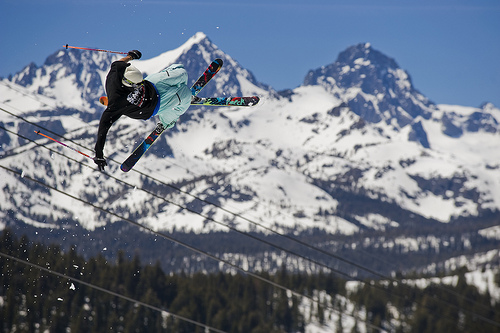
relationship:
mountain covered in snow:
[0, 31, 500, 262] [2, 91, 443, 232]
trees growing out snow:
[0, 217, 499, 328] [133, 131, 347, 236]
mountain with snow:
[6, 44, 99, 144] [0, 77, 73, 115]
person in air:
[89, 47, 198, 169] [0, 0, 500, 327]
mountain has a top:
[0, 31, 500, 262] [55, 27, 399, 67]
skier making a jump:
[89, 47, 198, 169] [14, 15, 287, 232]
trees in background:
[0, 217, 499, 328] [5, 190, 495, 259]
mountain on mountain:
[0, 31, 500, 262] [0, 31, 500, 262]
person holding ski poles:
[89, 47, 198, 169] [31, 37, 124, 161]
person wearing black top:
[89, 47, 198, 169] [90, 58, 140, 155]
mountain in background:
[0, 31, 500, 262] [0, 0, 500, 327]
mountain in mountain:
[0, 31, 500, 262] [0, 31, 500, 262]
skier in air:
[89, 47, 198, 169] [0, 0, 500, 327]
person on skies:
[89, 47, 198, 169] [116, 58, 266, 173]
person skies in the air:
[89, 47, 198, 169] [0, 0, 500, 327]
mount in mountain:
[298, 35, 451, 138] [0, 31, 500, 262]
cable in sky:
[0, 217, 499, 328] [0, 0, 500, 327]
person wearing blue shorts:
[89, 47, 198, 169] [146, 60, 196, 129]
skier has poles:
[89, 47, 198, 169] [31, 37, 124, 161]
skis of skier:
[116, 58, 266, 173] [89, 47, 198, 169]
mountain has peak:
[298, 35, 451, 138] [326, 33, 400, 69]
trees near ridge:
[2, 159, 497, 273] [89, 162, 413, 255]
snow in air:
[22, 211, 130, 269] [0, 0, 500, 327]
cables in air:
[5, 143, 499, 333] [0, 0, 500, 327]